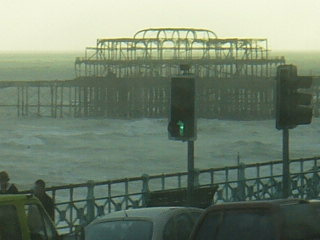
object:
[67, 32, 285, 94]
structure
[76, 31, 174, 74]
framework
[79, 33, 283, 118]
building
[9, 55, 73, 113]
extension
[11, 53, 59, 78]
water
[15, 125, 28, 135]
waves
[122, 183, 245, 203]
hoods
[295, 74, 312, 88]
cover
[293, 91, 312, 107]
cover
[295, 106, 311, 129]
cover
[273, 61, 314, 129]
traffic light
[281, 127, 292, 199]
pole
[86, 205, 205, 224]
roof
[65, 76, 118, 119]
structure frame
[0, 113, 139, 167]
water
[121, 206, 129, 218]
antenna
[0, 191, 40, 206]
roof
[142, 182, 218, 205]
bench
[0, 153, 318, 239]
railing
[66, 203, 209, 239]
car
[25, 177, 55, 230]
man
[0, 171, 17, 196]
man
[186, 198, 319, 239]
car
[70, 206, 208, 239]
car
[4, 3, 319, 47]
sky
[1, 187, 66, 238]
car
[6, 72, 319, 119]
pier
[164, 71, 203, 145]
traffic light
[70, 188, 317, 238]
roadway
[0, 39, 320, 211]
ocean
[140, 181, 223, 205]
bench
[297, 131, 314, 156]
water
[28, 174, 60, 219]
pedestrian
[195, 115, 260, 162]
water